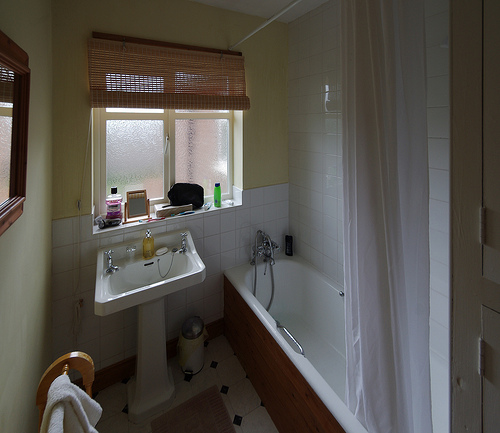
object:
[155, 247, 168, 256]
bar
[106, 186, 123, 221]
bottle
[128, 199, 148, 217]
mirror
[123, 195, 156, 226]
stand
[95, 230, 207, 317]
sink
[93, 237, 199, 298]
sink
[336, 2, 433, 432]
shower curtain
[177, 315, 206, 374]
garbage can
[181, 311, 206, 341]
lid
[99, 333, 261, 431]
tile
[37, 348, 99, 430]
rack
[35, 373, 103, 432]
towel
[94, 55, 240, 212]
window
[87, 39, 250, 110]
bamboo shade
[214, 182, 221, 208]
shower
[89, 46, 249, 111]
blind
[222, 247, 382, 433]
bathtub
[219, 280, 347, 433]
wood side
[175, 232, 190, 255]
tap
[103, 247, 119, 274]
tap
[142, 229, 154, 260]
hand soap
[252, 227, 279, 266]
tap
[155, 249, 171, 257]
soap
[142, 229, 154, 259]
bottle